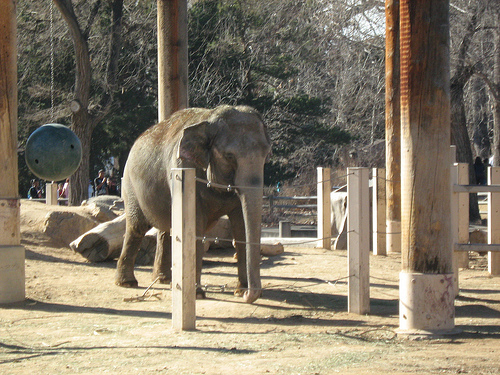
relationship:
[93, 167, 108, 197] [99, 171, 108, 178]
man holding camera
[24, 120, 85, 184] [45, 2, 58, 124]
ball on a chain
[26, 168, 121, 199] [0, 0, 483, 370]
people walking next to zoo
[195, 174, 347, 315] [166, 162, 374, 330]
rope between poles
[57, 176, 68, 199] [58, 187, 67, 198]
woman carrying a purse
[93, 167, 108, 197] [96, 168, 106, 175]
man wearing a ballcap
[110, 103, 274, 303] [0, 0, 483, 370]
elephant in an zoo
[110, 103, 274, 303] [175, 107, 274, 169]
elephant has ears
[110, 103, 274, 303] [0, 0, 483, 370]
elephant in zoo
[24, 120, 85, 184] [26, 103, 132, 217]
ball in air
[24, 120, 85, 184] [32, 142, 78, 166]
ball has holes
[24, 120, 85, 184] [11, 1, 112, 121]
ball hanging from air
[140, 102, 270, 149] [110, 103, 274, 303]
patch on elephant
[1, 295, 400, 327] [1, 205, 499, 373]
shadow on ground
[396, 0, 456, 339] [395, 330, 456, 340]
pole  cemented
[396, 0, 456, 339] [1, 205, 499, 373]
pole to ground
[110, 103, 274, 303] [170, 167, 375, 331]
elephant in fence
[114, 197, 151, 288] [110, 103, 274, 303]
leg of elephant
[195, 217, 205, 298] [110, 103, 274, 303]
leg of elephant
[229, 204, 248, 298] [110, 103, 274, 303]
leg of elephant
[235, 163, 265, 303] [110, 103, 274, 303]
trunk of elephant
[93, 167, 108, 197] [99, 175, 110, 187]
man holding camera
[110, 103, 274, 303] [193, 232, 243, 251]
elephant in front of rope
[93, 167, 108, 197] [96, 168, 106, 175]
man wearing ballcap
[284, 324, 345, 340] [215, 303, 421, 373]
straw on ground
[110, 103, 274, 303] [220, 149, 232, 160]
elephant has eye